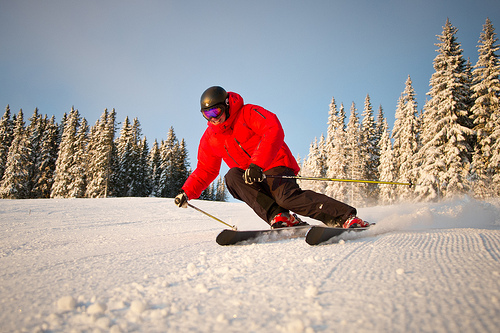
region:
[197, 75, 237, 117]
Man is wearing protective helmet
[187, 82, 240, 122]
Man's helmet is black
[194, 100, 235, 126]
Man wearing protective goggles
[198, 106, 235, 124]
Goggle lens are tinted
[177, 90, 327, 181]
Man is wearing orange ski jacket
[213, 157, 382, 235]
Man is wearing warm brown pants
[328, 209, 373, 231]
Man's ski boot is orange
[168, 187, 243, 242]
Man pushing himself using ski pole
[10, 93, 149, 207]
Pine trees are dusted with snow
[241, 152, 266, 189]
Man is wearing warm glove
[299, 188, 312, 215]
man is wearing black pants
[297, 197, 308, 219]
man is wearing black pants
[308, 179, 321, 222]
man is wearing black pants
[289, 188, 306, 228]
man is wearing black pants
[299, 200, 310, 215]
man is wearing black pants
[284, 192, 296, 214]
man is wearing black pants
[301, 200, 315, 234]
man is wearing black pants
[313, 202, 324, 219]
man is wearing black pants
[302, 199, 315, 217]
man is wearing black pants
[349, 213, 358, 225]
the shoe is red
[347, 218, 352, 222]
the shoe is red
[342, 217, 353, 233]
the shoe is red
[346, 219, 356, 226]
the shoe is red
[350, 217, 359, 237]
the shoe is red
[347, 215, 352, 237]
the shoe is red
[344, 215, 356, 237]
the shoe is red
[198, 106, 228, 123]
purple glasses on skiier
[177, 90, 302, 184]
orange jacket on skiier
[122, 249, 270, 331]
snow skiier is on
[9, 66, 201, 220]
evergreen trees in back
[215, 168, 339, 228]
sweatpants on the skiier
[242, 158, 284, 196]
gloves on the skiier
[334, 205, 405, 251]
left foot of skiier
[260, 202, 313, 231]
right foot of skiier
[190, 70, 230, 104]
helmet of the skiier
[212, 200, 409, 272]
skis of the skiier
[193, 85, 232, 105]
Black helmet on man's head.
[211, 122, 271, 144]
Man wearing red jacket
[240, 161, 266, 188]
Black gloves on man's hand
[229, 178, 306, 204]
Man is wearing black pants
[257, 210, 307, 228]
Man wearing black and red sneakers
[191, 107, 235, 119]
Red visor on mans helmet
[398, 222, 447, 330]
White snow on ground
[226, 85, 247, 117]
Red hood on jacket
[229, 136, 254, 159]
Black zipper on jacket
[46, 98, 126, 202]
Snow filled pine trees